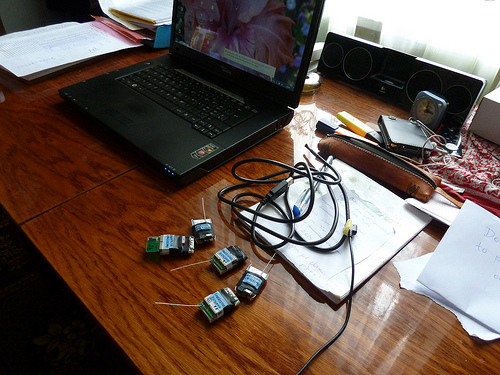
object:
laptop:
[57, 0, 327, 187]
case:
[316, 134, 444, 202]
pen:
[293, 155, 334, 218]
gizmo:
[146, 234, 195, 256]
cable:
[217, 144, 356, 375]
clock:
[409, 91, 449, 131]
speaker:
[317, 31, 486, 130]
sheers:
[327, 0, 500, 33]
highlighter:
[336, 110, 385, 145]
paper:
[390, 254, 500, 342]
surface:
[3, 52, 498, 375]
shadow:
[176, 128, 295, 210]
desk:
[2, 34, 498, 374]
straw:
[154, 302, 202, 307]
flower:
[234, 0, 300, 43]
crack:
[15, 165, 143, 228]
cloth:
[423, 104, 499, 209]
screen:
[172, 2, 322, 93]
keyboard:
[114, 62, 261, 140]